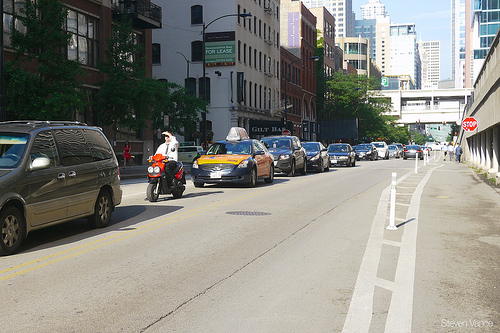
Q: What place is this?
A: It is a city.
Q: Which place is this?
A: It is a city.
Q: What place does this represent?
A: It represents the city.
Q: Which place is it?
A: It is a city.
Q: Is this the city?
A: Yes, it is the city.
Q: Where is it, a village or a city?
A: It is a city.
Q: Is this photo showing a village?
A: No, the picture is showing a city.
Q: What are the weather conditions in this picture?
A: It is sunny.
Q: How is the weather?
A: It is sunny.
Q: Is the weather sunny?
A: Yes, it is sunny.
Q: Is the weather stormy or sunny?
A: It is sunny.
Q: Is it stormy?
A: No, it is sunny.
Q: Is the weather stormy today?
A: No, it is sunny.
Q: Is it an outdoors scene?
A: Yes, it is outdoors.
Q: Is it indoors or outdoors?
A: It is outdoors.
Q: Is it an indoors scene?
A: No, it is outdoors.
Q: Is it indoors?
A: No, it is outdoors.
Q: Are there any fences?
A: No, there are no fences.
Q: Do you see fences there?
A: No, there are no fences.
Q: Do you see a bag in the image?
A: No, there are no bags.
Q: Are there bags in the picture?
A: No, there are no bags.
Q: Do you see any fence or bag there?
A: No, there are no bags or fences.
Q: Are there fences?
A: No, there are no fences.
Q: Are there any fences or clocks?
A: No, there are no fences or clocks.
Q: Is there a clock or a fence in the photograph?
A: No, there are no fences or clocks.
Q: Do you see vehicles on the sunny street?
A: Yes, there are vehicles on the street.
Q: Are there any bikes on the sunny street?
A: No, there are vehicles on the street.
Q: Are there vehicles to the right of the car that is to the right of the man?
A: Yes, there are vehicles to the right of the car.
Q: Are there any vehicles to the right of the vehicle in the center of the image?
A: Yes, there are vehicles to the right of the car.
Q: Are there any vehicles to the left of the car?
A: No, the vehicles are to the right of the car.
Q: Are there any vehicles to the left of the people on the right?
A: Yes, there are vehicles to the left of the people.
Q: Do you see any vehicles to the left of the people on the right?
A: Yes, there are vehicles to the left of the people.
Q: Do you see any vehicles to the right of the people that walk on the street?
A: No, the vehicles are to the left of the people.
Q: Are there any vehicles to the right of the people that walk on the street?
A: No, the vehicles are to the left of the people.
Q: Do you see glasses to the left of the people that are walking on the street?
A: No, there are vehicles to the left of the people.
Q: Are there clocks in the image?
A: No, there are no clocks.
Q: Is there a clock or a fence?
A: No, there are no clocks or fences.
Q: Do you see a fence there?
A: No, there are no fences.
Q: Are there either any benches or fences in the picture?
A: No, there are no fences or benches.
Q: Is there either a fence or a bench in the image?
A: No, there are no fences or benches.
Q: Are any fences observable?
A: No, there are no fences.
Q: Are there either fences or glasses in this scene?
A: No, there are no fences or glasses.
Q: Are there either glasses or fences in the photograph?
A: No, there are no fences or glasses.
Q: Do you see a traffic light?
A: No, there are no traffic lights.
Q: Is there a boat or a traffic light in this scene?
A: No, there are no traffic lights or boats.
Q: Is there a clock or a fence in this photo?
A: No, there are no fences or clocks.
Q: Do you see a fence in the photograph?
A: No, there are no fences.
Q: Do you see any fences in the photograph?
A: No, there are no fences.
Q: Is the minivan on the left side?
A: Yes, the minivan is on the left of the image.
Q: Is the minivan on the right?
A: No, the minivan is on the left of the image.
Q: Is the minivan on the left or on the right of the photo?
A: The minivan is on the left of the image.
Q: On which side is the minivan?
A: The minivan is on the left of the image.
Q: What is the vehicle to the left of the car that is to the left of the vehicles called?
A: The vehicle is a minivan.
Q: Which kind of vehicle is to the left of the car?
A: The vehicle is a minivan.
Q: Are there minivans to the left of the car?
A: Yes, there is a minivan to the left of the car.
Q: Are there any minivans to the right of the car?
A: No, the minivan is to the left of the car.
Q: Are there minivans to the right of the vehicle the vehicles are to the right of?
A: No, the minivan is to the left of the car.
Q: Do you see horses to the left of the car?
A: No, there is a minivan to the left of the car.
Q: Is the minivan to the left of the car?
A: Yes, the minivan is to the left of the car.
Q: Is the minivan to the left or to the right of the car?
A: The minivan is to the left of the car.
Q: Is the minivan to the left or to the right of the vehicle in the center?
A: The minivan is to the left of the car.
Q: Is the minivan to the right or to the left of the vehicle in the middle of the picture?
A: The minivan is to the left of the car.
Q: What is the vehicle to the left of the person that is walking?
A: The vehicle is a minivan.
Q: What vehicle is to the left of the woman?
A: The vehicle is a minivan.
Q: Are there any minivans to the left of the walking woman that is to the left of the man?
A: Yes, there is a minivan to the left of the woman.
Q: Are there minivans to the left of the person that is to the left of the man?
A: Yes, there is a minivan to the left of the woman.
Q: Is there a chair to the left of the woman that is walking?
A: No, there is a minivan to the left of the woman.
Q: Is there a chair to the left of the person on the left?
A: No, there is a minivan to the left of the woman.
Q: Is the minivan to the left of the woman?
A: Yes, the minivan is to the left of the woman.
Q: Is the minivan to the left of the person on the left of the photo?
A: Yes, the minivan is to the left of the woman.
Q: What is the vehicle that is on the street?
A: The vehicle is a minivan.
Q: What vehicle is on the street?
A: The vehicle is a minivan.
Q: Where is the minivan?
A: The minivan is on the street.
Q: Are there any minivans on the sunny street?
A: Yes, there is a minivan on the street.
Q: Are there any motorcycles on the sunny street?
A: No, there is a minivan on the street.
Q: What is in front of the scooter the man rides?
A: The minivan is in front of the scooter.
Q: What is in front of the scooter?
A: The minivan is in front of the scooter.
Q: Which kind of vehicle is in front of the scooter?
A: The vehicle is a minivan.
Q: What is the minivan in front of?
A: The minivan is in front of the scooter.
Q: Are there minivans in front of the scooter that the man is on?
A: Yes, there is a minivan in front of the scooter.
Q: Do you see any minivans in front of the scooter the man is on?
A: Yes, there is a minivan in front of the scooter.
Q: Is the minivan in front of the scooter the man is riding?
A: Yes, the minivan is in front of the scooter.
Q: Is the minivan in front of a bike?
A: No, the minivan is in front of the scooter.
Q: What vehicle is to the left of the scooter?
A: The vehicle is a minivan.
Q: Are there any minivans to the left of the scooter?
A: Yes, there is a minivan to the left of the scooter.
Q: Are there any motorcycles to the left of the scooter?
A: No, there is a minivan to the left of the scooter.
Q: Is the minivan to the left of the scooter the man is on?
A: Yes, the minivan is to the left of the scooter.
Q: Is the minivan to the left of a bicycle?
A: No, the minivan is to the left of the scooter.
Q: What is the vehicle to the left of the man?
A: The vehicle is a minivan.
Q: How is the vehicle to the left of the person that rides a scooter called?
A: The vehicle is a minivan.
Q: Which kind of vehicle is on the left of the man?
A: The vehicle is a minivan.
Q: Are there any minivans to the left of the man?
A: Yes, there is a minivan to the left of the man.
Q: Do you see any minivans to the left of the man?
A: Yes, there is a minivan to the left of the man.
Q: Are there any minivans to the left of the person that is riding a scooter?
A: Yes, there is a minivan to the left of the man.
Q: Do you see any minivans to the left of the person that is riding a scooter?
A: Yes, there is a minivan to the left of the man.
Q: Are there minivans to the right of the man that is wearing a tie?
A: No, the minivan is to the left of the man.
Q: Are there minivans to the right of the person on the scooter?
A: No, the minivan is to the left of the man.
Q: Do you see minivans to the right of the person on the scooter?
A: No, the minivan is to the left of the man.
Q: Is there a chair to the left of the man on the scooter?
A: No, there is a minivan to the left of the man.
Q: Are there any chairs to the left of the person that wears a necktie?
A: No, there is a minivan to the left of the man.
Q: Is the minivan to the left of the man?
A: Yes, the minivan is to the left of the man.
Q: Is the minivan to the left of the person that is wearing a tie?
A: Yes, the minivan is to the left of the man.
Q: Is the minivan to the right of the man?
A: No, the minivan is to the left of the man.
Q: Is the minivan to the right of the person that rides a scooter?
A: No, the minivan is to the left of the man.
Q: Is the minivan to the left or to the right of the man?
A: The minivan is to the left of the man.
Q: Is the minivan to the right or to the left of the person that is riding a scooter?
A: The minivan is to the left of the man.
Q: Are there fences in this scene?
A: No, there are no fences.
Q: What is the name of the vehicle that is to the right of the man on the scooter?
A: The vehicle is a car.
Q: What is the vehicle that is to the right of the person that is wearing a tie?
A: The vehicle is a car.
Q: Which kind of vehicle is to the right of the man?
A: The vehicle is a car.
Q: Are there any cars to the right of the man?
A: Yes, there is a car to the right of the man.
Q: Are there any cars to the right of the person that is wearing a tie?
A: Yes, there is a car to the right of the man.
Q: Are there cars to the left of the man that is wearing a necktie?
A: No, the car is to the right of the man.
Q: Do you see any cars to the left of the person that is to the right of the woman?
A: No, the car is to the right of the man.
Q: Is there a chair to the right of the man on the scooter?
A: No, there is a car to the right of the man.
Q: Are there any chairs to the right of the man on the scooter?
A: No, there is a car to the right of the man.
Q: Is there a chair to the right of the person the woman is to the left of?
A: No, there is a car to the right of the man.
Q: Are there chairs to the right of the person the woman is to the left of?
A: No, there is a car to the right of the man.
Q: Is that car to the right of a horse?
A: No, the car is to the right of a man.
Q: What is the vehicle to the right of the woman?
A: The vehicle is a car.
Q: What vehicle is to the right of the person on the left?
A: The vehicle is a car.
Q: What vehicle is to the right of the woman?
A: The vehicle is a car.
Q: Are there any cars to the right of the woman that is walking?
A: Yes, there is a car to the right of the woman.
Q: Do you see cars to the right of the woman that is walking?
A: Yes, there is a car to the right of the woman.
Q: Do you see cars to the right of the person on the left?
A: Yes, there is a car to the right of the woman.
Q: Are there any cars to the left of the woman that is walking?
A: No, the car is to the right of the woman.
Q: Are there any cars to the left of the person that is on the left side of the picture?
A: No, the car is to the right of the woman.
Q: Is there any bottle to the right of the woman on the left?
A: No, there is a car to the right of the woman.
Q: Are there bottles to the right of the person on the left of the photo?
A: No, there is a car to the right of the woman.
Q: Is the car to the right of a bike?
A: No, the car is to the right of a woman.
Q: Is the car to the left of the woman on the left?
A: No, the car is to the right of the woman.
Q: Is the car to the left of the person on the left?
A: No, the car is to the right of the woman.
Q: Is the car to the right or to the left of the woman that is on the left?
A: The car is to the right of the woman.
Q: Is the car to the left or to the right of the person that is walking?
A: The car is to the right of the woman.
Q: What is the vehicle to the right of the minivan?
A: The vehicle is a car.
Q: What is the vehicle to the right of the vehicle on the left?
A: The vehicle is a car.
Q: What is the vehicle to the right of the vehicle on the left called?
A: The vehicle is a car.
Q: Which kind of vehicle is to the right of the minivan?
A: The vehicle is a car.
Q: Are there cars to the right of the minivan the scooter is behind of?
A: Yes, there is a car to the right of the minivan.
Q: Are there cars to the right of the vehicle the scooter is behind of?
A: Yes, there is a car to the right of the minivan.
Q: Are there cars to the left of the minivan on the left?
A: No, the car is to the right of the minivan.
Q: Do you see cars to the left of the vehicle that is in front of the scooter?
A: No, the car is to the right of the minivan.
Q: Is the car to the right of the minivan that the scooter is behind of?
A: Yes, the car is to the right of the minivan.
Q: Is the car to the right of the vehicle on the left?
A: Yes, the car is to the right of the minivan.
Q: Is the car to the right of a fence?
A: No, the car is to the right of the minivan.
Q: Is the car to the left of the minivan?
A: No, the car is to the right of the minivan.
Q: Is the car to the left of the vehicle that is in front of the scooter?
A: No, the car is to the right of the minivan.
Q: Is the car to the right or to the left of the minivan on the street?
A: The car is to the right of the minivan.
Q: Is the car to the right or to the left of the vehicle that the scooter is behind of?
A: The car is to the right of the minivan.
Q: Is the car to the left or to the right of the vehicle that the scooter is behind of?
A: The car is to the right of the minivan.